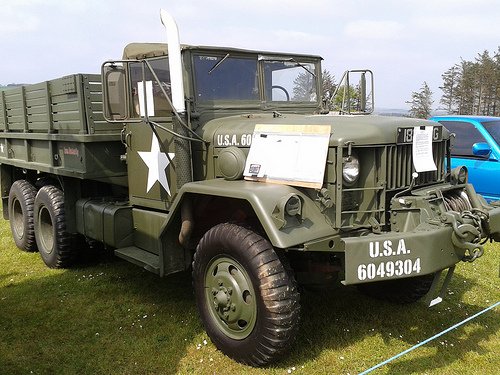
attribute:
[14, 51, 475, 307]
lorry — parked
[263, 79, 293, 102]
wheel — black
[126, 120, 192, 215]
door — closed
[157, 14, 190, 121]
chimney — white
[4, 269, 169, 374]
grass — short, green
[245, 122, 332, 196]
flyer — attached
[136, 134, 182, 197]
emblem — star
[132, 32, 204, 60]
roof — tarp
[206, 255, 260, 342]
hubcaps — green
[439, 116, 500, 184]
truck — blue, green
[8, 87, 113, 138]
bed —  truck's, with slats, framed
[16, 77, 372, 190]
vehicle — parked